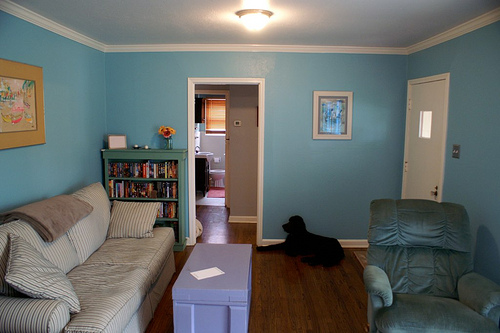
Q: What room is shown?
A: It is a living room.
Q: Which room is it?
A: It is a living room.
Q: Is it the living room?
A: Yes, it is the living room.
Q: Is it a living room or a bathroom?
A: It is a living room.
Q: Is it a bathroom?
A: No, it is a living room.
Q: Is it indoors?
A: Yes, it is indoors.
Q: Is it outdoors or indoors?
A: It is indoors.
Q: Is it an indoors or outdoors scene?
A: It is indoors.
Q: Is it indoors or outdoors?
A: It is indoors.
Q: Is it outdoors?
A: No, it is indoors.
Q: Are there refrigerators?
A: No, there are no refrigerators.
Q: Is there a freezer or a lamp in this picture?
A: No, there are no refrigerators or lamps.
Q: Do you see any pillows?
A: Yes, there is a pillow.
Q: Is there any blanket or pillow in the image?
A: Yes, there is a pillow.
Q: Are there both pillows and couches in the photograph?
A: Yes, there are both a pillow and a couch.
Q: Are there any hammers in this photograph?
A: No, there are no hammers.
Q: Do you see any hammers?
A: No, there are no hammers.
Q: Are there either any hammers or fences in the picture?
A: No, there are no hammers or fences.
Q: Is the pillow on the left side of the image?
A: Yes, the pillow is on the left of the image.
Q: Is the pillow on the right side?
A: No, the pillow is on the left of the image.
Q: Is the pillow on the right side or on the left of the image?
A: The pillow is on the left of the image.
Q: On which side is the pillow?
A: The pillow is on the left of the image.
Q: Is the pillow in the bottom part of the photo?
A: Yes, the pillow is in the bottom of the image.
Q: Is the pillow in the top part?
A: No, the pillow is in the bottom of the image.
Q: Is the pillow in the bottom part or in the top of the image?
A: The pillow is in the bottom of the image.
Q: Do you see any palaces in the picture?
A: No, there are no palaces.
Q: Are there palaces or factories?
A: No, there are no palaces or factories.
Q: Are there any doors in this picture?
A: Yes, there is a door.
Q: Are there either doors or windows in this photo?
A: Yes, there is a door.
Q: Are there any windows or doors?
A: Yes, there is a door.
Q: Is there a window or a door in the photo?
A: Yes, there is a door.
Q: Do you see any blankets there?
A: Yes, there is a blanket.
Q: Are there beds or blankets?
A: Yes, there is a blanket.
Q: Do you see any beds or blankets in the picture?
A: Yes, there is a blanket.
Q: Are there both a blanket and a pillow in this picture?
A: Yes, there are both a blanket and a pillow.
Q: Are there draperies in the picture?
A: No, there are no draperies.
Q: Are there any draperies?
A: No, there are no draperies.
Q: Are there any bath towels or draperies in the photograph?
A: No, there are no draperies or bath towels.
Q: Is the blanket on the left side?
A: Yes, the blanket is on the left of the image.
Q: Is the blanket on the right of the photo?
A: No, the blanket is on the left of the image.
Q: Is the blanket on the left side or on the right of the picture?
A: The blanket is on the left of the image.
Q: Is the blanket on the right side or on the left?
A: The blanket is on the left of the image.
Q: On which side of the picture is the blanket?
A: The blanket is on the left of the image.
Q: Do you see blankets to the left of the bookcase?
A: Yes, there is a blanket to the left of the bookcase.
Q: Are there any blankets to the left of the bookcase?
A: Yes, there is a blanket to the left of the bookcase.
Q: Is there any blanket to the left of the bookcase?
A: Yes, there is a blanket to the left of the bookcase.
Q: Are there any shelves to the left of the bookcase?
A: No, there is a blanket to the left of the bookcase.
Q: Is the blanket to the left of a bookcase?
A: Yes, the blanket is to the left of a bookcase.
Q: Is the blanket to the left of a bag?
A: No, the blanket is to the left of a bookcase.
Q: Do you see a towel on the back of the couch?
A: No, there is a blanket on the back of the couch.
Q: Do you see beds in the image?
A: No, there are no beds.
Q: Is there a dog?
A: Yes, there is a dog.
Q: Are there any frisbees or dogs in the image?
A: Yes, there is a dog.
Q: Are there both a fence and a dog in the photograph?
A: No, there is a dog but no fences.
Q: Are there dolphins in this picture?
A: No, there are no dolphins.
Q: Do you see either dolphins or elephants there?
A: No, there are no dolphins or elephants.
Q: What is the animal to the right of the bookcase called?
A: The animal is a dog.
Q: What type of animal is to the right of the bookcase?
A: The animal is a dog.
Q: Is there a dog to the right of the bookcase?
A: Yes, there is a dog to the right of the bookcase.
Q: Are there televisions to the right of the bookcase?
A: No, there is a dog to the right of the bookcase.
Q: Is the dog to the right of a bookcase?
A: Yes, the dog is to the right of a bookcase.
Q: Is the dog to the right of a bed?
A: No, the dog is to the right of a bookcase.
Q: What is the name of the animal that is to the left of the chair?
A: The animal is a dog.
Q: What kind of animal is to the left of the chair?
A: The animal is a dog.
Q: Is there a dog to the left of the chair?
A: Yes, there is a dog to the left of the chair.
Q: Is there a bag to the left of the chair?
A: No, there is a dog to the left of the chair.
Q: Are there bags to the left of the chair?
A: No, there is a dog to the left of the chair.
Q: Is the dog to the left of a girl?
A: No, the dog is to the left of the chair.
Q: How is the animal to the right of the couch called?
A: The animal is a dog.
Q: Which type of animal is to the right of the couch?
A: The animal is a dog.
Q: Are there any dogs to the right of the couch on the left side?
A: Yes, there is a dog to the right of the couch.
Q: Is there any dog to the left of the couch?
A: No, the dog is to the right of the couch.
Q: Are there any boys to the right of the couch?
A: No, there is a dog to the right of the couch.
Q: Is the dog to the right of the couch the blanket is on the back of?
A: Yes, the dog is to the right of the couch.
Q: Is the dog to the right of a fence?
A: No, the dog is to the right of the couch.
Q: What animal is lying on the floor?
A: The dog is lying on the floor.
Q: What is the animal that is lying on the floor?
A: The animal is a dog.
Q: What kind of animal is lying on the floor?
A: The animal is a dog.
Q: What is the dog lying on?
A: The dog is lying on the floor.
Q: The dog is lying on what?
A: The dog is lying on the floor.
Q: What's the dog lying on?
A: The dog is lying on the floor.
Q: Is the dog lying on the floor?
A: Yes, the dog is lying on the floor.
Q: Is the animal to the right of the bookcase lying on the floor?
A: Yes, the dog is lying on the floor.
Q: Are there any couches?
A: Yes, there is a couch.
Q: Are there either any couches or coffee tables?
A: Yes, there is a couch.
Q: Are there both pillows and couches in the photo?
A: Yes, there are both a couch and a pillow.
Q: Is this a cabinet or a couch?
A: This is a couch.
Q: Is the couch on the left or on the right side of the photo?
A: The couch is on the left of the image.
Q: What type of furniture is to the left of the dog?
A: The piece of furniture is a couch.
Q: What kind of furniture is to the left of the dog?
A: The piece of furniture is a couch.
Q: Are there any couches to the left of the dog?
A: Yes, there is a couch to the left of the dog.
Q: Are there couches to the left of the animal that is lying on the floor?
A: Yes, there is a couch to the left of the dog.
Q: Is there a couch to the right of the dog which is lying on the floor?
A: No, the couch is to the left of the dog.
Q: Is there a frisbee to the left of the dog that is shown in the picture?
A: No, there is a couch to the left of the dog.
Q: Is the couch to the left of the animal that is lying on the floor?
A: Yes, the couch is to the left of the dog.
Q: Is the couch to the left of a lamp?
A: No, the couch is to the left of the dog.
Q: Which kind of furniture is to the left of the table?
A: The piece of furniture is a couch.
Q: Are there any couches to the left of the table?
A: Yes, there is a couch to the left of the table.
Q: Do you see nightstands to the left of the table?
A: No, there is a couch to the left of the table.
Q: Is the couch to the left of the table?
A: Yes, the couch is to the left of the table.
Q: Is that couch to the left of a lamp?
A: No, the couch is to the left of the table.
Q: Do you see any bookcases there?
A: Yes, there is a bookcase.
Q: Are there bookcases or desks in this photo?
A: Yes, there is a bookcase.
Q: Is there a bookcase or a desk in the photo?
A: Yes, there is a bookcase.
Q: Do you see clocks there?
A: No, there are no clocks.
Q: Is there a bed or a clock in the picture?
A: No, there are no clocks or beds.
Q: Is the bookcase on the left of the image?
A: Yes, the bookcase is on the left of the image.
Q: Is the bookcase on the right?
A: No, the bookcase is on the left of the image.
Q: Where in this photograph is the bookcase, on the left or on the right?
A: The bookcase is on the left of the image.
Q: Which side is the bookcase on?
A: The bookcase is on the left of the image.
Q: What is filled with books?
A: The bookcase is filled with books.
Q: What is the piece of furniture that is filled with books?
A: The piece of furniture is a bookcase.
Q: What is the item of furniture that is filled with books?
A: The piece of furniture is a bookcase.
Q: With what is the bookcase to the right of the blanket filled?
A: The bookcase is filled with books.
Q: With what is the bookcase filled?
A: The bookcase is filled with books.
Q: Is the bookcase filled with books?
A: Yes, the bookcase is filled with books.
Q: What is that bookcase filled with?
A: The bookcase is filled with books.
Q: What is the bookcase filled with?
A: The bookcase is filled with books.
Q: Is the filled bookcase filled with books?
A: Yes, the bookcase is filled with books.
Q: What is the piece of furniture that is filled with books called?
A: The piece of furniture is a bookcase.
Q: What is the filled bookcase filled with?
A: The bookcase is filled with books.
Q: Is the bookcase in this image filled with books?
A: Yes, the bookcase is filled with books.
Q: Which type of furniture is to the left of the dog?
A: The piece of furniture is a bookcase.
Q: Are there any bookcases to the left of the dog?
A: Yes, there is a bookcase to the left of the dog.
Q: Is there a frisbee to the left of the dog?
A: No, there is a bookcase to the left of the dog.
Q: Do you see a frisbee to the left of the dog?
A: No, there is a bookcase to the left of the dog.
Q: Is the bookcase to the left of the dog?
A: Yes, the bookcase is to the left of the dog.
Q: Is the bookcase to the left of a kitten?
A: No, the bookcase is to the left of the dog.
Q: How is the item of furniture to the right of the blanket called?
A: The piece of furniture is a bookcase.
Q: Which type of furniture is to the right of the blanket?
A: The piece of furniture is a bookcase.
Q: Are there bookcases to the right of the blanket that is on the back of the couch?
A: Yes, there is a bookcase to the right of the blanket.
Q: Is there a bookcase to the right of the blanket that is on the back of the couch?
A: Yes, there is a bookcase to the right of the blanket.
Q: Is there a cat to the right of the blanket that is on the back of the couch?
A: No, there is a bookcase to the right of the blanket.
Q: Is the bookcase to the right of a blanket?
A: Yes, the bookcase is to the right of a blanket.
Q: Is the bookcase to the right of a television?
A: No, the bookcase is to the right of a blanket.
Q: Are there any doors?
A: Yes, there is a door.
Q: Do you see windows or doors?
A: Yes, there is a door.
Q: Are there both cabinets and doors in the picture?
A: No, there is a door but no cabinets.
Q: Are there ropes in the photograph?
A: No, there are no ropes.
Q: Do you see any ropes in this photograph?
A: No, there are no ropes.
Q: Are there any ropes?
A: No, there are no ropes.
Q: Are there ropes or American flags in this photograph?
A: No, there are no ropes or American flags.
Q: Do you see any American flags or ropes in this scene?
A: No, there are no ropes or American flags.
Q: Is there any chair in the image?
A: Yes, there is a chair.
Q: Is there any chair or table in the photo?
A: Yes, there is a chair.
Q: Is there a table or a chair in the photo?
A: Yes, there is a chair.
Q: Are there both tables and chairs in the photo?
A: Yes, there are both a chair and a table.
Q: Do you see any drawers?
A: No, there are no drawers.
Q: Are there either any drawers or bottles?
A: No, there are no drawers or bottles.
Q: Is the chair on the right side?
A: Yes, the chair is on the right of the image.